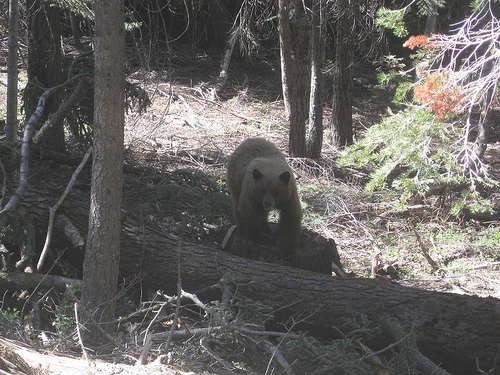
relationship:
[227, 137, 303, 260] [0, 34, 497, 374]
bear on ground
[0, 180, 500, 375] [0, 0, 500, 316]
log in forest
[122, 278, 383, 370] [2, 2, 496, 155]
sticks in forest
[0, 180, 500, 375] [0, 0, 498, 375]
log in forest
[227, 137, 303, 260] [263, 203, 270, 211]
bear has nose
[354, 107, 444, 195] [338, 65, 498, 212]
green leaves on branches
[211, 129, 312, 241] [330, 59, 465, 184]
bear in forest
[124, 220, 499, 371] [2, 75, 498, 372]
log on ground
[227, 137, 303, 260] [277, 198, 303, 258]
bear has front legs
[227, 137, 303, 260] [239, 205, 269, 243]
bear has front legs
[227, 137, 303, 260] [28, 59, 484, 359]
bear crawling through woods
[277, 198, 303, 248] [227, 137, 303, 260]
front legs of bear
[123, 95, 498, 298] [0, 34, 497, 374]
grass in ground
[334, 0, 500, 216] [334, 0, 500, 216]
branch on branch